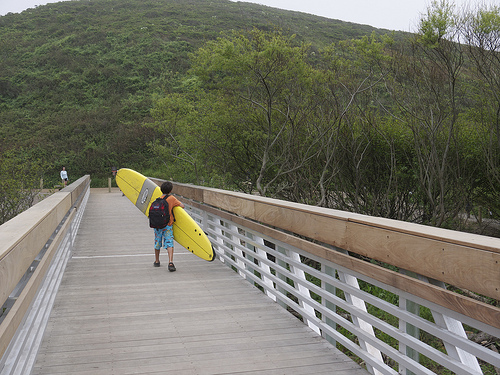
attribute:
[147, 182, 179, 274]
boy — little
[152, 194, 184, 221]
shirt — short sleeve, orange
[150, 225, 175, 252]
shorts — blue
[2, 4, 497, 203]
mountain — beautiful, green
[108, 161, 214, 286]
boy — little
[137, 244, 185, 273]
sandles — leather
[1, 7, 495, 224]
green trees — beautiful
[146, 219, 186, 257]
shorts — blue, floral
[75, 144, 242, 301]
board — yellow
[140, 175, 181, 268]
boy — little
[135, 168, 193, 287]
boy — little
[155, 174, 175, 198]
hair — dark brown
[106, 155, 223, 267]
surfboard — yellow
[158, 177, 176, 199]
hair — short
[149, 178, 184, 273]
boy — little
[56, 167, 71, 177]
shirt — white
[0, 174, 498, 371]
bridge — wooden